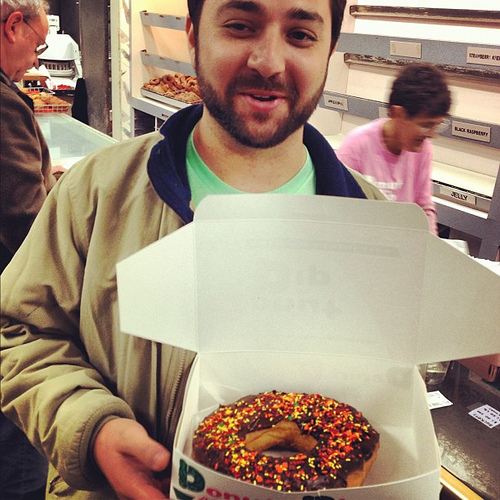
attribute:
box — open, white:
[128, 189, 487, 499]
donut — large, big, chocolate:
[212, 388, 352, 500]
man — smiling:
[17, 0, 438, 481]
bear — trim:
[222, 107, 291, 162]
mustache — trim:
[244, 66, 302, 109]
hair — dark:
[190, 1, 212, 38]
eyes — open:
[231, 10, 332, 71]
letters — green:
[160, 464, 208, 500]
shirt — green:
[182, 133, 320, 227]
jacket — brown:
[6, 112, 207, 480]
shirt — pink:
[344, 118, 440, 203]